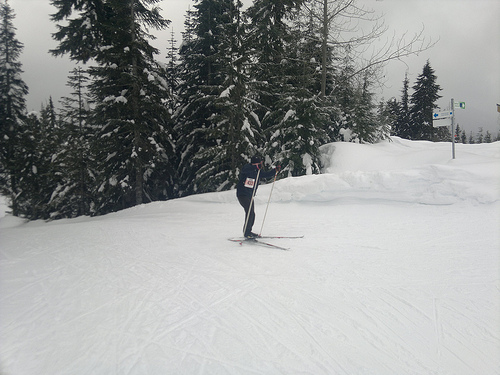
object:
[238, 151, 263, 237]
man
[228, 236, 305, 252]
skis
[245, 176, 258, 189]
bib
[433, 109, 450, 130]
sign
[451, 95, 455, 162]
pole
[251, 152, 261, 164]
beanie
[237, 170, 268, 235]
poles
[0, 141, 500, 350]
snow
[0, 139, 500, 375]
ground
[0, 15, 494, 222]
trees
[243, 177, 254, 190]
number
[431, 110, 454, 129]
direction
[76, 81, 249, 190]
leaves